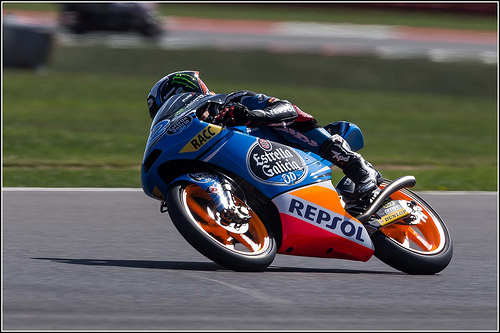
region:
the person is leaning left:
[92, 35, 480, 297]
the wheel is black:
[115, 164, 292, 283]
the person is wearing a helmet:
[140, 56, 217, 123]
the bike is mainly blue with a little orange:
[90, 65, 388, 301]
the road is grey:
[183, 257, 400, 318]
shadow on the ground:
[14, 214, 229, 291]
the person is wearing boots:
[302, 112, 382, 199]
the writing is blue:
[250, 178, 370, 245]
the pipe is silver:
[352, 160, 432, 215]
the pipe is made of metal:
[348, 158, 428, 223]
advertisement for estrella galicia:
[246, 135, 308, 187]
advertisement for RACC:
[177, 121, 223, 153]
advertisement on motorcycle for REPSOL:
[270, 187, 375, 247]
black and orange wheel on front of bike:
[165, 170, 280, 270]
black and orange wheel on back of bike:
[351, 175, 452, 275]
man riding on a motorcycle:
[140, 65, 385, 196]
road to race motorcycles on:
[2, 185, 497, 330]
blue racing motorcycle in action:
[136, 90, 452, 273]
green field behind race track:
[1, 21, 494, 191]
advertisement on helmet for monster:
[167, 71, 201, 93]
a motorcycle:
[156, 104, 455, 293]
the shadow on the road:
[131, 247, 179, 274]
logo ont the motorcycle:
[242, 149, 307, 183]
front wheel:
[173, 186, 275, 266]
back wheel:
[395, 233, 452, 269]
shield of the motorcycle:
[161, 102, 180, 111]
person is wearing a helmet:
[153, 74, 189, 89]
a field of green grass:
[24, 99, 84, 144]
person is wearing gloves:
[221, 103, 253, 123]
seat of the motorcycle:
[325, 119, 350, 136]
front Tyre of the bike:
[168, 189, 275, 272]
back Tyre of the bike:
[377, 180, 454, 274]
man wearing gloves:
[218, 103, 249, 123]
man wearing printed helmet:
[148, 71, 198, 105]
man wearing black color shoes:
[317, 139, 379, 193]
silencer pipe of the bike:
[386, 174, 415, 200]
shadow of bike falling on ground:
[43, 252, 197, 270]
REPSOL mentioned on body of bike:
[286, 198, 364, 241]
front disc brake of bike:
[207, 195, 249, 232]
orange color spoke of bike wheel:
[185, 191, 207, 217]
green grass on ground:
[1, 52, 494, 184]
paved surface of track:
[5, 192, 496, 327]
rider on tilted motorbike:
[139, 71, 454, 275]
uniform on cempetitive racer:
[220, 90, 378, 191]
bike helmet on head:
[146, 69, 210, 119]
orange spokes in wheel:
[363, 174, 455, 270]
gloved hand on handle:
[215, 101, 251, 126]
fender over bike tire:
[166, 169, 236, 217]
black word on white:
[287, 198, 368, 243]